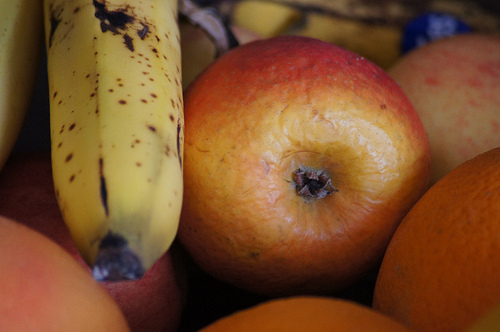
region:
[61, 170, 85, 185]
brown spot on banana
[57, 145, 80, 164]
brown spot on banana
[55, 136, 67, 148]
brown spot on banana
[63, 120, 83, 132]
brown spot on banana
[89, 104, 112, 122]
brown spot on banana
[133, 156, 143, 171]
brown spot on banana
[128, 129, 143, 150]
brown spot on banana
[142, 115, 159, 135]
brown spot on banana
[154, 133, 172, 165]
brown spot on banana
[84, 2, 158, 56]
brown spot on banana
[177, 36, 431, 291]
a wrinkled red apple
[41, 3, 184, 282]
black and brown spots on a banana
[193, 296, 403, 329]
a blurry orange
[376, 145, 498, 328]
a orange with two gray colored spots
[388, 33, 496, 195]
a yellow colored apple that is a little blurry with red spots on it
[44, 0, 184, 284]
banana is slightly overripe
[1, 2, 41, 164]
a ripe yellow banana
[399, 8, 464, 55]
a round blue object with white writing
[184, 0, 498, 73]
the background is very blurry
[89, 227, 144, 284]
the end of a banana is triangular shape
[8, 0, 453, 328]
Fruit in a basket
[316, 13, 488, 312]
Fruit in a basket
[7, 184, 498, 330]
Fruit in a basket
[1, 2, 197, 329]
Fruit in a basket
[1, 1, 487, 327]
a close-up of fruit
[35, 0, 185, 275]
a banana next to an apple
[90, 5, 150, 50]
bruises on the banana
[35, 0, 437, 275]
banana and apple are overripe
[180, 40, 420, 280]
apple skin is wrinkly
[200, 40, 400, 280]
bottom of apple is facing screen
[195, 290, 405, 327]
orange underneath the apple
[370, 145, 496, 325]
orange beside the apple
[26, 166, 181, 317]
red apple underneath banana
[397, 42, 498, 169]
apple behind the apple in the center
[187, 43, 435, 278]
the bottom of an apple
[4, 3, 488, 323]
several different kinds of fruit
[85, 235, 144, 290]
the end of a banana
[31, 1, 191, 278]
a yellow banana with spots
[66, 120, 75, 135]
a spot on a yellow banana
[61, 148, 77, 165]
a spot on a yellow banana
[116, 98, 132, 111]
a spot on a yellow banana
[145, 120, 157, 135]
a spot on a yellow banana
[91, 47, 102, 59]
a spot on a yellow banana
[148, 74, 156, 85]
a spot on a yellow banana